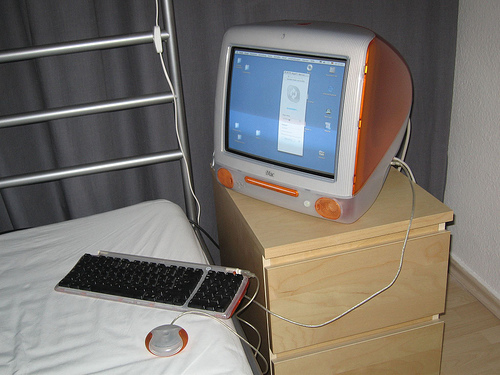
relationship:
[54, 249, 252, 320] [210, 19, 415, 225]
keyboard for monitor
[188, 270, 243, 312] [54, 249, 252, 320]
pad on keyboard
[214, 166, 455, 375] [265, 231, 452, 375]
nightstand has drawers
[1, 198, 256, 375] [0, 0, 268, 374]
mattress on bed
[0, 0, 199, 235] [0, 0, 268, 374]
headboard of bed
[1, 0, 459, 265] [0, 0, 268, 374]
curtains behind bed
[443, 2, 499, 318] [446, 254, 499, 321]
wall has baseboard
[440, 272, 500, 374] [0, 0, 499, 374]
floor of room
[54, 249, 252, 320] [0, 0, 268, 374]
keyboard on bed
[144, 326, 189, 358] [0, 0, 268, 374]
mouse on bed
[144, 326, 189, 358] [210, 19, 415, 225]
mouse for monitor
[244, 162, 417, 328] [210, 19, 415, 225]
cord for monitor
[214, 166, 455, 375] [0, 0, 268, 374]
nightstand near bed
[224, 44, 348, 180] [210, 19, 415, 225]
monitor on monitor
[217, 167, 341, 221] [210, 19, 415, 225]
speakers on monitor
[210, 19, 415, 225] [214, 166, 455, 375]
monitor on nightstand